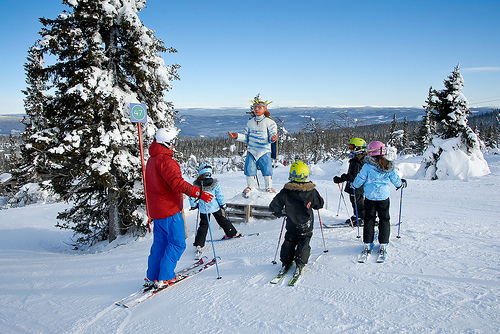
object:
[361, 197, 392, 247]
pants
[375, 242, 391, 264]
skis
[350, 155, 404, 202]
jacket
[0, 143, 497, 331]
mound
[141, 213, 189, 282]
pants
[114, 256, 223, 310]
skis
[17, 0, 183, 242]
tree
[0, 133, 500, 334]
snow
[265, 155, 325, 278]
child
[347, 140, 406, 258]
child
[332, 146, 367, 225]
child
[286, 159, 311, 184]
helmet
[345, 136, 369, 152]
helmet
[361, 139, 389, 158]
helmet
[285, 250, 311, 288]
ski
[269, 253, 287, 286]
ski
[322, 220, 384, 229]
ski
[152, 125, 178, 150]
helmet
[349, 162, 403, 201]
blue sweater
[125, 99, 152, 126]
sign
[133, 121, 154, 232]
red pole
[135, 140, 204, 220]
jacket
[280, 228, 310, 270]
black pants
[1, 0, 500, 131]
sky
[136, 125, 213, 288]
skier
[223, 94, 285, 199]
statue